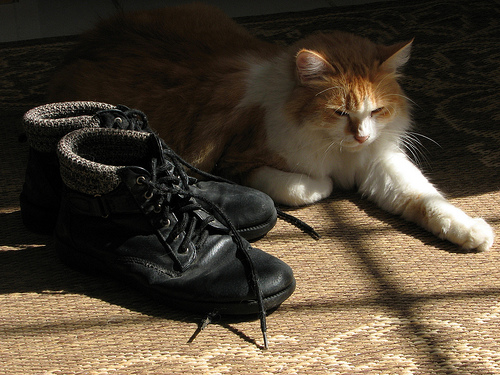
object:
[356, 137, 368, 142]
nose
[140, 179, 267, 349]
shoe lace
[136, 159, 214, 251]
laces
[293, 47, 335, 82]
cat ear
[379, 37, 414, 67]
cat ear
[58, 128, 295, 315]
black boots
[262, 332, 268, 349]
ends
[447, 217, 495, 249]
paw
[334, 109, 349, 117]
eyes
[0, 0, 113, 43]
wall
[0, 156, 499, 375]
pane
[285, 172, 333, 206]
paws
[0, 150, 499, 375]
carpet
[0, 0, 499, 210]
shadow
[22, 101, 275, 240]
booties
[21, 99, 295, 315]
pair boots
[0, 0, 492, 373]
floor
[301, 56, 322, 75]
hair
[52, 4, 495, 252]
cat